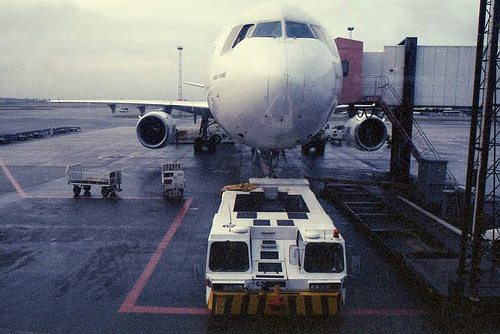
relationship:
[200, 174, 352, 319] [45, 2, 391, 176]
machine in front of airport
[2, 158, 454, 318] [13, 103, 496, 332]
line on pavement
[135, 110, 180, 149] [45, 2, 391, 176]
engine on airport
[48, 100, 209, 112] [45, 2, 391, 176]
wing on airport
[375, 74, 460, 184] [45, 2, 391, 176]
stairs next to airport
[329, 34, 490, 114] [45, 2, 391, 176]
corridor on a airport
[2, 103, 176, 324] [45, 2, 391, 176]
runway by a airport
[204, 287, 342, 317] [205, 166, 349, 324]
paint on a refueling truck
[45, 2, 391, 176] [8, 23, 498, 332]
airport at a airport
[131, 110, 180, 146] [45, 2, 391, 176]
engine on a airport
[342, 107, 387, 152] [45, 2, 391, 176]
engine on a airport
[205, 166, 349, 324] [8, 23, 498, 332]
refueling truck at a airport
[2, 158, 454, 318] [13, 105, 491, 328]
line on ground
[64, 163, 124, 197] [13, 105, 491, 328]
transporter on ground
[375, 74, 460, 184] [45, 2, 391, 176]
stairs to airport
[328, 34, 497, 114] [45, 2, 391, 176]
transporter to airport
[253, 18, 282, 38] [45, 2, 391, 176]
window to airport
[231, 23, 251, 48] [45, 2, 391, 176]
window to airport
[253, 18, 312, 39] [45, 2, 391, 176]
windshield on front of airport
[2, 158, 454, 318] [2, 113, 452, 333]
line on runway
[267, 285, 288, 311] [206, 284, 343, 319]
fixture on stripes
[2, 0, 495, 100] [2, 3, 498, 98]
clouds in sky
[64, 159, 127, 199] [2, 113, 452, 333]
cart on runway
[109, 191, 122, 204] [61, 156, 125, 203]
tire on vehicle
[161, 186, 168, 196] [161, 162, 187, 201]
tire on carts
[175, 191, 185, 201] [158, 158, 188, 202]
tire on vehicle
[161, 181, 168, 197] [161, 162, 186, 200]
tire on vehicle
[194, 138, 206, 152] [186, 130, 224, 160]
tire on vehicle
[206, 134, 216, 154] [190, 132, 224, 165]
tire on vehicle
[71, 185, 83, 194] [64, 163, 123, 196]
tire on cart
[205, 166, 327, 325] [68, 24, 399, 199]
refueling truck by plane